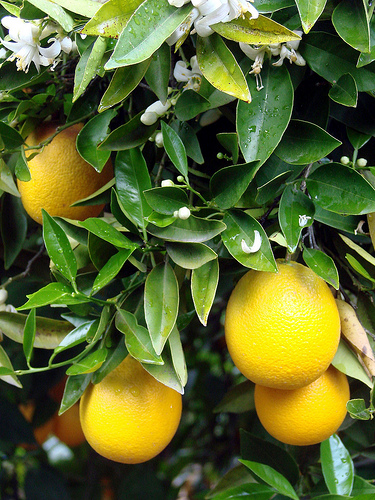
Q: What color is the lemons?
A: Yellow.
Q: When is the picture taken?
A: During the day.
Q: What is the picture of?
A: Lemons.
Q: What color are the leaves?
A: Green.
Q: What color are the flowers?
A: White.